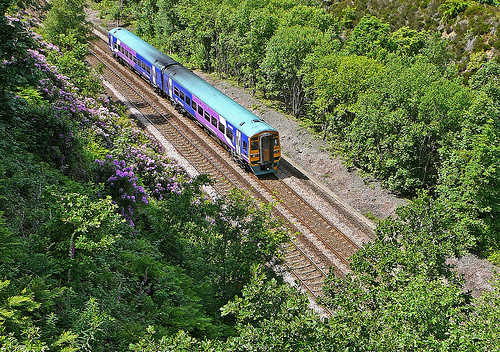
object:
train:
[109, 27, 280, 176]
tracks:
[177, 113, 392, 317]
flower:
[26, 47, 184, 225]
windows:
[147, 66, 150, 74]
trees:
[276, 43, 415, 150]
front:
[249, 130, 282, 175]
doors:
[236, 130, 242, 156]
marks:
[252, 119, 260, 123]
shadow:
[129, 91, 183, 128]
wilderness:
[193, 23, 437, 171]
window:
[219, 122, 225, 134]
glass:
[198, 105, 203, 116]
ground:
[210, 192, 441, 302]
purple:
[116, 41, 137, 67]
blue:
[172, 79, 196, 118]